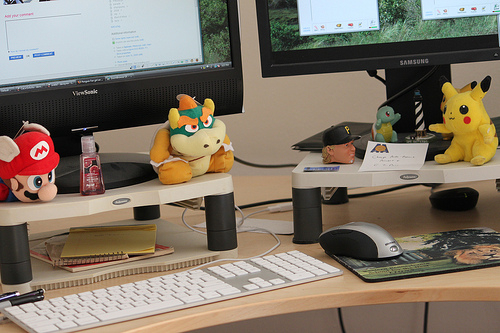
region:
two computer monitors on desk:
[54, 2, 471, 95]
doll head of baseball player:
[316, 121, 361, 164]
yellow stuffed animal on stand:
[428, 78, 497, 173]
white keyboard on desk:
[34, 242, 305, 330]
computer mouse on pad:
[319, 214, 404, 269]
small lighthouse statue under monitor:
[401, 83, 442, 147]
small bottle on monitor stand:
[74, 129, 111, 200]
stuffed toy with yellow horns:
[140, 91, 236, 188]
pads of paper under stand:
[46, 217, 166, 269]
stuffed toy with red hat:
[4, 119, 64, 209]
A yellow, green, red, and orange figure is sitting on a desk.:
[139, 86, 246, 194]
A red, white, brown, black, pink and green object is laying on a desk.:
[0, 111, 69, 218]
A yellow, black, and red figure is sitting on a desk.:
[418, 66, 498, 181]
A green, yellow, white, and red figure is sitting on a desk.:
[367, 98, 404, 154]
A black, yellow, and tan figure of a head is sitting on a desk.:
[312, 118, 362, 168]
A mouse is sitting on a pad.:
[310, 213, 412, 269]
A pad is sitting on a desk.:
[313, 216, 498, 284]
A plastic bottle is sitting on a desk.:
[68, 125, 108, 204]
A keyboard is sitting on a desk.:
[0, 235, 352, 332]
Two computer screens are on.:
[0, 0, 499, 145]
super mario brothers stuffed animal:
[0, 124, 70, 207]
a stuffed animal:
[128, 76, 265, 191]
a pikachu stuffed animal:
[415, 68, 499, 183]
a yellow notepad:
[48, 226, 172, 260]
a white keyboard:
[13, 230, 343, 331]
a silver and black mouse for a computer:
[308, 209, 450, 274]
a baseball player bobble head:
[288, 117, 425, 187]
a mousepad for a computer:
[319, 206, 499, 275]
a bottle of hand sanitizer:
[59, 124, 126, 206]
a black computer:
[0, 0, 262, 210]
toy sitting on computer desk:
[0, 123, 58, 202]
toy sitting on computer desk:
[152, 93, 232, 180]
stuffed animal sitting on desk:
[434, 83, 498, 166]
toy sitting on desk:
[370, 107, 404, 142]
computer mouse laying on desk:
[321, 218, 403, 263]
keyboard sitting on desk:
[8, 248, 344, 308]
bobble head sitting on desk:
[321, 121, 358, 163]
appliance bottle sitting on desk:
[78, 133, 114, 195]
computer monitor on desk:
[2, 28, 249, 115]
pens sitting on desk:
[3, 273, 51, 313]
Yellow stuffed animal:
[427, 82, 499, 168]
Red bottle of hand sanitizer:
[72, 127, 109, 197]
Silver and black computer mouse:
[317, 217, 407, 264]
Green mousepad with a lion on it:
[325, 221, 499, 283]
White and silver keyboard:
[7, 234, 334, 331]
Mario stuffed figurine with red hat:
[0, 115, 67, 207]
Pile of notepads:
[40, 222, 166, 272]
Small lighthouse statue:
[398, 90, 433, 145]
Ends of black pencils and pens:
[0, 278, 76, 310]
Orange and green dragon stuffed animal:
[132, 92, 247, 185]